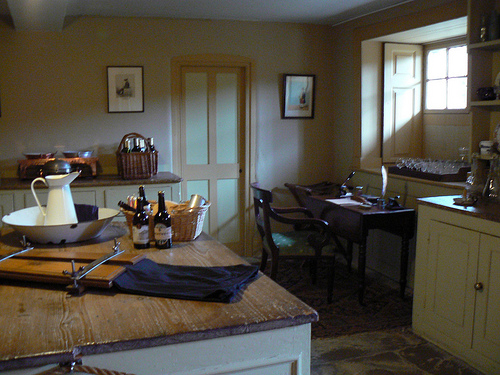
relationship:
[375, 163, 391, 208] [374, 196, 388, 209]
quill in a bottle of ink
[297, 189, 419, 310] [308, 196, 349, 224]
desk made of wood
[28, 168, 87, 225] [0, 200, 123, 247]
water pitcher in a basin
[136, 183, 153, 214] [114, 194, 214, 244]
wine in basket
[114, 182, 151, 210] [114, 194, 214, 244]
wine bottles in a basket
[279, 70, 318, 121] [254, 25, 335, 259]
frame on wall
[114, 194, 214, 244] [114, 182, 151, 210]
basket full of wine bottles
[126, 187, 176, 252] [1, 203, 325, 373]
wine bottles on top of table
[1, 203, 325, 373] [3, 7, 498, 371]
table in kitchen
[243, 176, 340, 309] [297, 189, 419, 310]
chair at a table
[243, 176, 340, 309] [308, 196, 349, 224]
chair made of wood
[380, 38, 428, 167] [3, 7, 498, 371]
window shutter in kitchen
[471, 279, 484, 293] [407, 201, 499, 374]
knob on cabinet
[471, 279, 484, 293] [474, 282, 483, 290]
knob made of knob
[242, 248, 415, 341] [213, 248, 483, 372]
rug on floor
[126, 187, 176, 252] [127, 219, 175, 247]
wine bottles has white labels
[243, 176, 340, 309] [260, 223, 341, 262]
chair has cushion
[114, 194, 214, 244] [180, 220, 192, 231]
basket light brown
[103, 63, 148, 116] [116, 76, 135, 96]
picture of person sitting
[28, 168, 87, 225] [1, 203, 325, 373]
water pitcher on top of table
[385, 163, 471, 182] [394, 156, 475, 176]
tray filled with glasses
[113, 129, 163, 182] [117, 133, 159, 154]
basket with wine bottles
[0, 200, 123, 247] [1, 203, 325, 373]
basin on top of table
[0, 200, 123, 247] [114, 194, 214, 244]
basin near basket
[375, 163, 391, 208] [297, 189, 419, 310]
feather pen on top of desk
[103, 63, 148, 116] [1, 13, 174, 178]
photograph on wall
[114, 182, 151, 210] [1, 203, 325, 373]
wine bottles on top of table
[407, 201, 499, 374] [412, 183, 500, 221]
cabinet underneath couter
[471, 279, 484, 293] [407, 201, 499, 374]
knob to open cabinet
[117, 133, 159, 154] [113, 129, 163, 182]
wine bottles in basket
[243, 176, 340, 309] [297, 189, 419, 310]
chair at desk